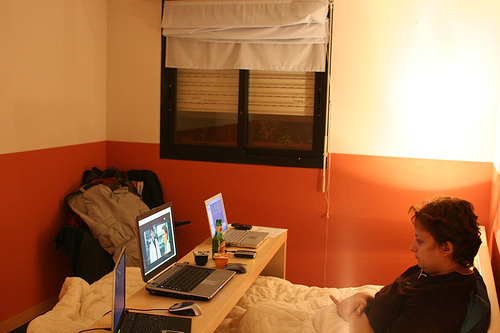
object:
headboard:
[468, 225, 500, 332]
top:
[136, 200, 179, 230]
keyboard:
[145, 263, 237, 301]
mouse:
[168, 301, 203, 316]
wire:
[126, 307, 166, 314]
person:
[328, 195, 491, 333]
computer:
[203, 192, 269, 250]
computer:
[110, 245, 193, 331]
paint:
[334, 14, 492, 247]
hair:
[406, 197, 483, 267]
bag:
[53, 166, 167, 285]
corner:
[97, 0, 113, 179]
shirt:
[363, 263, 491, 332]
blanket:
[216, 275, 380, 332]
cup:
[213, 253, 230, 269]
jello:
[213, 253, 229, 269]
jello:
[192, 249, 210, 266]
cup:
[192, 249, 210, 266]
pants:
[63, 183, 151, 268]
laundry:
[55, 166, 166, 266]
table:
[79, 221, 287, 333]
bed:
[23, 225, 500, 332]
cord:
[320, 2, 332, 193]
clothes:
[46, 116, 143, 229]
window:
[156, 0, 336, 170]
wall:
[92, 0, 500, 274]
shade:
[172, 10, 375, 103]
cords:
[322, 2, 333, 218]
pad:
[187, 262, 243, 298]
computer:
[134, 201, 238, 302]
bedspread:
[24, 266, 387, 333]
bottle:
[211, 218, 225, 261]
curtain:
[160, 0, 328, 72]